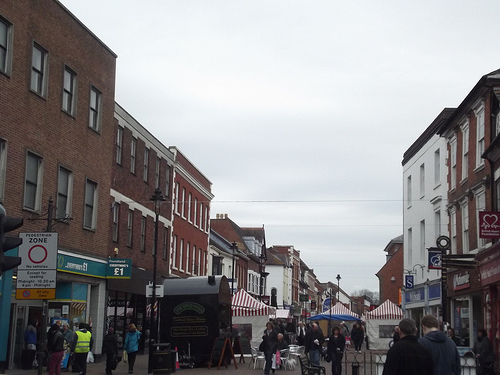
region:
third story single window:
[26, 35, 46, 91]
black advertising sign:
[210, 335, 235, 365]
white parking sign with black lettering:
[20, 230, 55, 300]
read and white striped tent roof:
[365, 295, 400, 315]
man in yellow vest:
[70, 320, 85, 365]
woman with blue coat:
[120, 320, 135, 365]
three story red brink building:
[171, 145, 208, 279]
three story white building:
[401, 117, 449, 336]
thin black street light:
[150, 186, 163, 358]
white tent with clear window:
[366, 312, 402, 349]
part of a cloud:
[273, 27, 340, 89]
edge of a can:
[191, 288, 223, 311]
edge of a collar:
[392, 332, 407, 355]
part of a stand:
[216, 337, 232, 368]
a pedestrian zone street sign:
[15, 231, 58, 301]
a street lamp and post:
[147, 186, 167, 340]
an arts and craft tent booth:
[230, 288, 275, 355]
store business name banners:
[400, 265, 419, 290]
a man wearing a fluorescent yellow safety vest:
[73, 329, 91, 353]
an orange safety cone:
[172, 345, 180, 368]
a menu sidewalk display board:
[206, 333, 238, 370]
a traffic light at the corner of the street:
[0, 203, 22, 278]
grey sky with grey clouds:
[215, 1, 405, 204]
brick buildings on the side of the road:
[1, 1, 208, 276]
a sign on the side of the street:
[15, 230, 58, 300]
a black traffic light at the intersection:
[0, 213, 24, 275]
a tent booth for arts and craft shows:
[363, 298, 402, 351]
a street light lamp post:
[149, 187, 166, 342]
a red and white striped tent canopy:
[230, 287, 276, 317]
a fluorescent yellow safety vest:
[71, 329, 92, 354]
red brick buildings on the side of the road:
[0, 0, 212, 280]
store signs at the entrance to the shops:
[402, 210, 497, 290]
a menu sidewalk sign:
[205, 331, 240, 370]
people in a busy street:
[23, 246, 497, 373]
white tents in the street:
[234, 281, 276, 358]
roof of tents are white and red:
[228, 286, 281, 320]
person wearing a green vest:
[60, 319, 105, 374]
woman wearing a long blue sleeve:
[116, 314, 144, 373]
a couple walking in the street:
[380, 311, 464, 373]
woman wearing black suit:
[317, 319, 353, 373]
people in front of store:
[0, 243, 111, 373]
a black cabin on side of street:
[154, 268, 245, 362]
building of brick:
[8, 5, 122, 261]